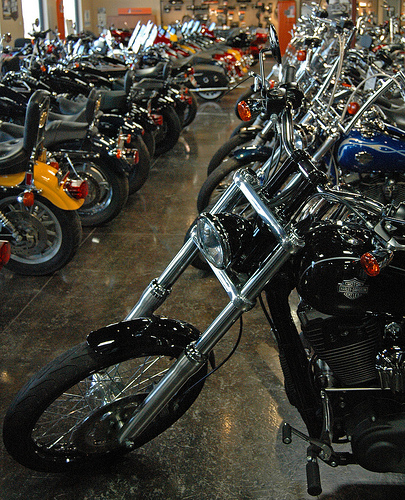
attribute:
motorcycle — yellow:
[0, 92, 89, 276]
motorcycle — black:
[32, 89, 124, 230]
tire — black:
[4, 341, 209, 475]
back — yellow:
[227, 46, 249, 77]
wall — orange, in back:
[88, 1, 314, 40]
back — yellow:
[34, 159, 85, 276]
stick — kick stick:
[280, 423, 331, 463]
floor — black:
[0, 76, 405, 499]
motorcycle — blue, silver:
[323, 134, 404, 202]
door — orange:
[278, 0, 301, 62]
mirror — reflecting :
[300, 0, 351, 23]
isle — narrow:
[4, 53, 280, 412]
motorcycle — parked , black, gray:
[2, 3, 402, 495]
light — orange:
[237, 97, 251, 122]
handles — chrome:
[310, 12, 350, 33]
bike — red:
[249, 33, 270, 55]